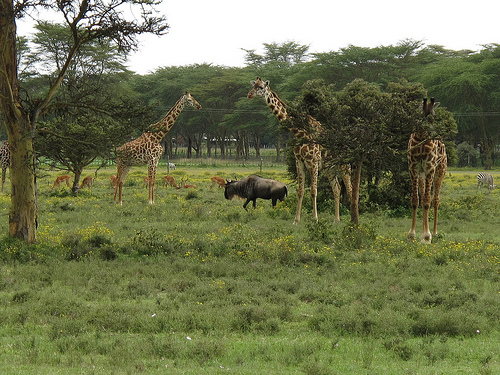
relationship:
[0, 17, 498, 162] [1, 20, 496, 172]
trees in background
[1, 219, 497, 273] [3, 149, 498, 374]
flowers in grass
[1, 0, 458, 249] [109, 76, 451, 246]
trees surrounding giraffes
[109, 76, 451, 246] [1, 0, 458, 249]
giraffes in trees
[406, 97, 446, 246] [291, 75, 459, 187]
giraffe eating leaves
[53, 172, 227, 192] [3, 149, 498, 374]
gazelles on grass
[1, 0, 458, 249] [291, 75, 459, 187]
trees have leaves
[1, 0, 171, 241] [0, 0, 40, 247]
tree has trunk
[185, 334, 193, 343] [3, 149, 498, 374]
paper on grass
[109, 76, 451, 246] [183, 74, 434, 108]
giraffes have horns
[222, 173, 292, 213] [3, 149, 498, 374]
animal in grass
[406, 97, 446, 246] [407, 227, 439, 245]
giraffe has feet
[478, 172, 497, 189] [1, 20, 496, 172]
zebra in background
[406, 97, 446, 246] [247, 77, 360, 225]
giraffe beside giraffe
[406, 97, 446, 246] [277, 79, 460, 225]
giraffe in tree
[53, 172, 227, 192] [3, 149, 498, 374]
gazelles eating grass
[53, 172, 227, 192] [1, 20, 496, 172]
gazelles in background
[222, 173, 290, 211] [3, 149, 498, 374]
wildebeest in grass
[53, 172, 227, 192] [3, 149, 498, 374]
gazelles in grass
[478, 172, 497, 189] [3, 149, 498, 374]
zebra munching on grass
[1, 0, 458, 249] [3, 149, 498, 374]
trees surrounding field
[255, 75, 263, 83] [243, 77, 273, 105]
horns on head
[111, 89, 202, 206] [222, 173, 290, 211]
giraffe watching wildebeest